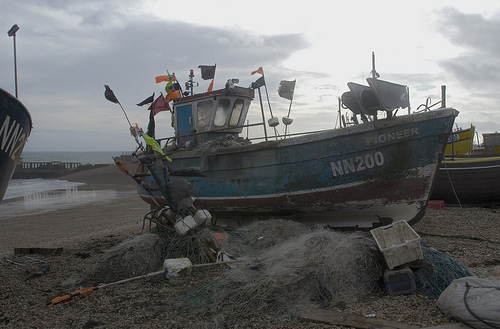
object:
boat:
[444, 126, 474, 162]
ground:
[443, 207, 496, 241]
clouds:
[0, 0, 500, 154]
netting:
[421, 249, 446, 284]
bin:
[368, 219, 425, 269]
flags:
[135, 64, 216, 118]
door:
[177, 104, 196, 146]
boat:
[109, 81, 460, 228]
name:
[363, 126, 420, 146]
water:
[0, 177, 82, 210]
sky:
[3, 2, 500, 152]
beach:
[0, 164, 147, 244]